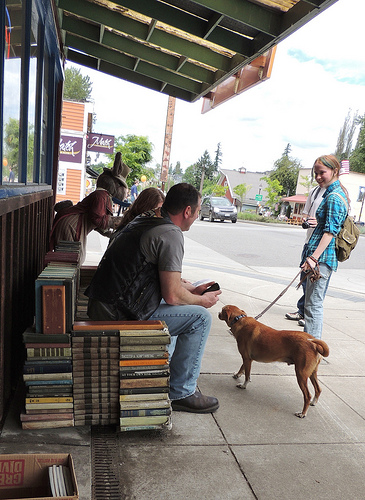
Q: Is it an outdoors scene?
A: Yes, it is outdoors.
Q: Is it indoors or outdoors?
A: It is outdoors.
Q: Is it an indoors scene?
A: No, it is outdoors.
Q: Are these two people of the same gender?
A: No, they are both male and female.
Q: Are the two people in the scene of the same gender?
A: No, they are both male and female.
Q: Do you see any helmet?
A: No, there are no helmets.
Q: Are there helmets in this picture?
A: No, there are no helmets.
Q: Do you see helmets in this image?
A: No, there are no helmets.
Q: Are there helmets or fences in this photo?
A: No, there are no helmets or fences.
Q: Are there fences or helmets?
A: No, there are no helmets or fences.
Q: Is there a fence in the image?
A: No, there are no fences.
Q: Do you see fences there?
A: No, there are no fences.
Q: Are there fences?
A: No, there are no fences.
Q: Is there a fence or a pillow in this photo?
A: No, there are no fences or pillows.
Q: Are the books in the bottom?
A: Yes, the books are in the bottom of the image.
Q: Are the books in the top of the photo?
A: No, the books are in the bottom of the image.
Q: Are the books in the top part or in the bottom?
A: The books are in the bottom of the image.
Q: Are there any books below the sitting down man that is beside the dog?
A: Yes, there are books below the man.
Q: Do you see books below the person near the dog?
A: Yes, there are books below the man.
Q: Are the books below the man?
A: Yes, the books are below the man.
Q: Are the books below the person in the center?
A: Yes, the books are below the man.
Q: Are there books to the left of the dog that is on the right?
A: Yes, there are books to the left of the dog.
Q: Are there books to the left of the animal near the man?
A: Yes, there are books to the left of the dog.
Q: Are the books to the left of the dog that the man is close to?
A: Yes, the books are to the left of the dog.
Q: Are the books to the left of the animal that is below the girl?
A: Yes, the books are to the left of the dog.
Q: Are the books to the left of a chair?
A: No, the books are to the left of the dog.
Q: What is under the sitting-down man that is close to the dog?
A: The books are under the man.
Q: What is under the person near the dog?
A: The books are under the man.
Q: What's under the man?
A: The books are under the man.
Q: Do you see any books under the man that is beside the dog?
A: Yes, there are books under the man.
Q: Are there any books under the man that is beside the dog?
A: Yes, there are books under the man.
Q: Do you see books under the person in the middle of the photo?
A: Yes, there are books under the man.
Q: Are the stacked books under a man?
A: Yes, the books are under a man.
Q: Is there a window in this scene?
A: Yes, there is a window.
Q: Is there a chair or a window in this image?
A: Yes, there is a window.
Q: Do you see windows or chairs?
A: Yes, there is a window.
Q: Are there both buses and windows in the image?
A: No, there is a window but no buses.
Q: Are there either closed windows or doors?
A: Yes, there is a closed window.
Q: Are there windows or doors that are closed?
A: Yes, the window is closed.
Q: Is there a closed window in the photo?
A: Yes, there is a closed window.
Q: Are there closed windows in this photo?
A: Yes, there is a closed window.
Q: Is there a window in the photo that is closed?
A: Yes, there is a window that is closed.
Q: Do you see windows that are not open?
A: Yes, there is an closed window.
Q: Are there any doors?
A: No, there are no doors.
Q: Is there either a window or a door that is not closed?
A: No, there is a window but it is closed.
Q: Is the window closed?
A: Yes, the window is closed.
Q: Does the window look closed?
A: Yes, the window is closed.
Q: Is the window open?
A: No, the window is closed.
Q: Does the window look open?
A: No, the window is closed.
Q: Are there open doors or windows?
A: No, there is a window but it is closed.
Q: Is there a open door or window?
A: No, there is a window but it is closed.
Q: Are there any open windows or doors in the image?
A: No, there is a window but it is closed.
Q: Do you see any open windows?
A: No, there is a window but it is closed.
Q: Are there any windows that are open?
A: No, there is a window but it is closed.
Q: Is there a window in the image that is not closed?
A: No, there is a window but it is closed.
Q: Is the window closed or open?
A: The window is closed.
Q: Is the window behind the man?
A: Yes, the window is behind the man.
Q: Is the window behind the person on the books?
A: Yes, the window is behind the man.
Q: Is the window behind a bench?
A: No, the window is behind the man.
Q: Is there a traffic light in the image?
A: No, there are no traffic lights.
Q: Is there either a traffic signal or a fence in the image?
A: No, there are no traffic lights or fences.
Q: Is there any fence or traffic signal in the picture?
A: No, there are no traffic lights or fences.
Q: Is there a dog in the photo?
A: Yes, there is a dog.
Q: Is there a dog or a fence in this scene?
A: Yes, there is a dog.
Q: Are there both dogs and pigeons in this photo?
A: No, there is a dog but no pigeons.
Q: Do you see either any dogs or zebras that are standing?
A: Yes, the dog is standing.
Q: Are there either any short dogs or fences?
A: Yes, there is a short dog.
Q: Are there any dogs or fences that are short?
A: Yes, the dog is short.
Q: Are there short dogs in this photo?
A: Yes, there is a short dog.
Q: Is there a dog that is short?
A: Yes, there is a dog that is short.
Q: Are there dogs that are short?
A: Yes, there is a dog that is short.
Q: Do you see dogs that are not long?
A: Yes, there is a short dog.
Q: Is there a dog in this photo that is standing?
A: Yes, there is a dog that is standing.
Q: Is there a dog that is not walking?
A: Yes, there is a dog that is standing.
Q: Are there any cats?
A: No, there are no cats.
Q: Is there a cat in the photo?
A: No, there are no cats.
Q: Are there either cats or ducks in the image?
A: No, there are no cats or ducks.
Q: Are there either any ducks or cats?
A: No, there are no cats or ducks.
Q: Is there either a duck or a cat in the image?
A: No, there are no cats or ducks.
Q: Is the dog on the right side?
A: Yes, the dog is on the right of the image.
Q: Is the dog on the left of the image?
A: No, the dog is on the right of the image.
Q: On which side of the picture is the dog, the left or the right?
A: The dog is on the right of the image.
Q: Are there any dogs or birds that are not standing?
A: No, there is a dog but it is standing.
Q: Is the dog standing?
A: Yes, the dog is standing.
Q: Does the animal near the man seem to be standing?
A: Yes, the dog is standing.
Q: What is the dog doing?
A: The dog is standing.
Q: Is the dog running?
A: No, the dog is standing.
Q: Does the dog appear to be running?
A: No, the dog is standing.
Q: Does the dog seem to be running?
A: No, the dog is standing.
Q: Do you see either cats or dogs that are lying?
A: No, there is a dog but it is standing.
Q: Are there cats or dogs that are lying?
A: No, there is a dog but it is standing.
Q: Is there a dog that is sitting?
A: No, there is a dog but it is standing.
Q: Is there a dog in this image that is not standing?
A: No, there is a dog but it is standing.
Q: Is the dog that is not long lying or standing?
A: The dog is standing.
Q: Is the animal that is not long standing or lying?
A: The dog is standing.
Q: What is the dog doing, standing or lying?
A: The dog is standing.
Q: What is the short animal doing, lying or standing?
A: The dog is standing.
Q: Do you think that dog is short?
A: Yes, the dog is short.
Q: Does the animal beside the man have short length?
A: Yes, the dog is short.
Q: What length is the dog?
A: The dog is short.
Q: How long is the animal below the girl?
A: The dog is short.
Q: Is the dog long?
A: No, the dog is short.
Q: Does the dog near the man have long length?
A: No, the dog is short.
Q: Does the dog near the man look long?
A: No, the dog is short.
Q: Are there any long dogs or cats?
A: No, there is a dog but it is short.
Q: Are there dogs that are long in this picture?
A: No, there is a dog but it is short.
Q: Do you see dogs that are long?
A: No, there is a dog but it is short.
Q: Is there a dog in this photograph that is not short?
A: No, there is a dog but it is short.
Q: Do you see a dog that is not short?
A: No, there is a dog but it is short.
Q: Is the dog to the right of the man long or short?
A: The dog is short.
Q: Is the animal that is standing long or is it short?
A: The dog is short.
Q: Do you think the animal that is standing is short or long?
A: The dog is short.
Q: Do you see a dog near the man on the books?
A: Yes, there is a dog near the man.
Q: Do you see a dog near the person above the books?
A: Yes, there is a dog near the man.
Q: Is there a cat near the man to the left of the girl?
A: No, there is a dog near the man.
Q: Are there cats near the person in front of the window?
A: No, there is a dog near the man.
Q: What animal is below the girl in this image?
A: The animal is a dog.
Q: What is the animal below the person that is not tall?
A: The animal is a dog.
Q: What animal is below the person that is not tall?
A: The animal is a dog.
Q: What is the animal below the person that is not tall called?
A: The animal is a dog.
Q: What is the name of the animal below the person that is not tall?
A: The animal is a dog.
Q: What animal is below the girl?
A: The animal is a dog.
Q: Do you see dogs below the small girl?
A: Yes, there is a dog below the girl.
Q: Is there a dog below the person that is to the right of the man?
A: Yes, there is a dog below the girl.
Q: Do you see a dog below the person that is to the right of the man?
A: Yes, there is a dog below the girl.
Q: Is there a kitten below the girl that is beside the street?
A: No, there is a dog below the girl.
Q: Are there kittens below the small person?
A: No, there is a dog below the girl.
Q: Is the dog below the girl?
A: Yes, the dog is below the girl.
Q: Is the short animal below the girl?
A: Yes, the dog is below the girl.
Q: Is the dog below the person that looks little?
A: Yes, the dog is below the girl.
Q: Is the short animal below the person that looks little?
A: Yes, the dog is below the girl.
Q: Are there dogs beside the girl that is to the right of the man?
A: Yes, there is a dog beside the girl.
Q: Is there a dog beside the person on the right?
A: Yes, there is a dog beside the girl.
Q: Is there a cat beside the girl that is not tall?
A: No, there is a dog beside the girl.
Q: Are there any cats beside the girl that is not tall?
A: No, there is a dog beside the girl.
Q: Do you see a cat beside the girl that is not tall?
A: No, there is a dog beside the girl.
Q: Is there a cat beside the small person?
A: No, there is a dog beside the girl.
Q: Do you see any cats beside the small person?
A: No, there is a dog beside the girl.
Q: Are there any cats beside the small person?
A: No, there is a dog beside the girl.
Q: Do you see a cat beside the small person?
A: No, there is a dog beside the girl.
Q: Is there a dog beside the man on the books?
A: Yes, there is a dog beside the man.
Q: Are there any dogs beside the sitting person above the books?
A: Yes, there is a dog beside the man.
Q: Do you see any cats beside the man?
A: No, there is a dog beside the man.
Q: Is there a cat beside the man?
A: No, there is a dog beside the man.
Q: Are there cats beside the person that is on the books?
A: No, there is a dog beside the man.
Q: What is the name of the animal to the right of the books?
A: The animal is a dog.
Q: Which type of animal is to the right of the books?
A: The animal is a dog.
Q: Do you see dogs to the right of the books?
A: Yes, there is a dog to the right of the books.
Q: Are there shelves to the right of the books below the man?
A: No, there is a dog to the right of the books.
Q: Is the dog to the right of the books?
A: Yes, the dog is to the right of the books.